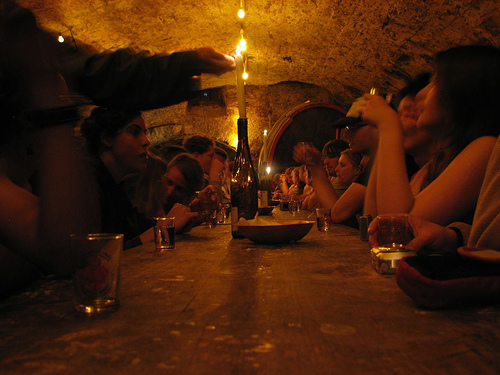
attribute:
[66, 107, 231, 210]
people — partying, inside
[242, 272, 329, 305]
table — wood, wooden, brown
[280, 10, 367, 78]
room — dark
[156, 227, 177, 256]
glass — small, half full, empty, clear, full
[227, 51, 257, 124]
candle — lit, on top, white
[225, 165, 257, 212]
bottle — black, dark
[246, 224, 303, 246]
bowl — wooden, small, empty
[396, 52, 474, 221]
woman — sitting, unhappy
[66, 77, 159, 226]
man — talking, clapping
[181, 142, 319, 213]
friends — talking, sitting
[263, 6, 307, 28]
ceiling — low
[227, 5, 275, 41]
light — reflected